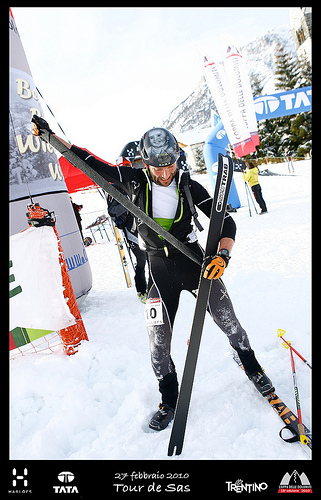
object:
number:
[150, 307, 157, 319]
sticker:
[142, 296, 163, 328]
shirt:
[152, 178, 178, 232]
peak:
[162, 30, 297, 129]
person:
[242, 160, 268, 216]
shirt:
[244, 166, 259, 186]